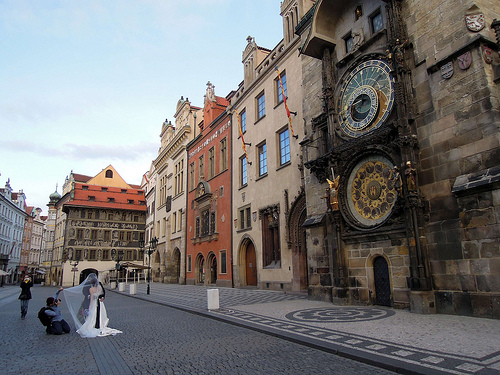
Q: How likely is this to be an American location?
A: Very unlikely.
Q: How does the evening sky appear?
A: Cloudless.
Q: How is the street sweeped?
A: Clean.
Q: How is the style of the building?
A: Older.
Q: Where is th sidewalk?
A: In front of buildings.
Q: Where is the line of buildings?
A: Next to each other.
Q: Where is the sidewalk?
A: In front of buildings.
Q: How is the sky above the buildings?
A: Bright blue.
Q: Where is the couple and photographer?
A: On street.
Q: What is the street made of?
A: Cobblestone.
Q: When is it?
A: Day time.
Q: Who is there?
A: People.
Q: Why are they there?
A: Taking pictures.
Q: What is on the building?
A: Clock.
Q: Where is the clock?
A: On the building.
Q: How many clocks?
A: 2.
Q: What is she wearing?
A: Dress.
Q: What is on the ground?
A: People.